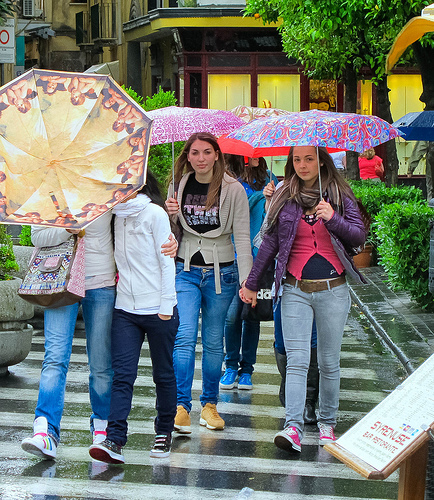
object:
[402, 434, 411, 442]
red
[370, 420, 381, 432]
letter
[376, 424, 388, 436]
letter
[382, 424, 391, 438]
letter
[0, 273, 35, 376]
flower pot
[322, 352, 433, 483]
sign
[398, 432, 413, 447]
letter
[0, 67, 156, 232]
umbrella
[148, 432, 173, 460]
sneakers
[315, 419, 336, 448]
sneakers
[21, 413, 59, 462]
sneakers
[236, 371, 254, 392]
sneakers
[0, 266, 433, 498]
sidewalk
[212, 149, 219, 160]
ear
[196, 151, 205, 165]
nose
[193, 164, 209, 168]
lips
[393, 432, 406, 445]
letter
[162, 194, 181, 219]
hand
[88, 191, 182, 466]
person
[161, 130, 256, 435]
person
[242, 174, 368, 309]
jacket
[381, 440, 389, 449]
letter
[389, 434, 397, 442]
red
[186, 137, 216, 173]
face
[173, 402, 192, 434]
shoe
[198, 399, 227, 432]
shoe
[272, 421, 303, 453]
shoes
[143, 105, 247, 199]
umbrella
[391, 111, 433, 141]
umbrella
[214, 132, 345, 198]
umbrella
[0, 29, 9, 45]
letter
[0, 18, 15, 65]
sign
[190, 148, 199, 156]
eye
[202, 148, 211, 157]
eye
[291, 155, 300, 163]
eye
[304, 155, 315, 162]
eye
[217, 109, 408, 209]
umbrella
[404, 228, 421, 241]
leaves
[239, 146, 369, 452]
girl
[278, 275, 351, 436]
pants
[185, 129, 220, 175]
head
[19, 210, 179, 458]
person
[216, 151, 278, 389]
person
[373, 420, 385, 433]
letter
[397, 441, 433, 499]
stand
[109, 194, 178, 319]
sweater